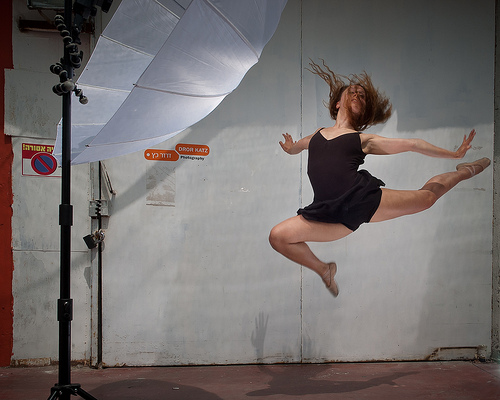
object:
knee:
[269, 221, 307, 258]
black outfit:
[297, 127, 386, 232]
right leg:
[266, 213, 321, 273]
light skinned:
[266, 58, 487, 297]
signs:
[174, 142, 211, 161]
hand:
[454, 129, 477, 159]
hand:
[279, 132, 293, 154]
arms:
[368, 138, 454, 158]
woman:
[269, 56, 490, 297]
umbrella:
[57, 0, 291, 169]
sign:
[20, 136, 64, 177]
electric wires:
[48, 11, 89, 99]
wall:
[0, 1, 494, 365]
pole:
[58, 11, 74, 386]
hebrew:
[178, 147, 208, 153]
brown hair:
[304, 57, 391, 131]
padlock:
[82, 232, 105, 249]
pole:
[96, 197, 103, 361]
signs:
[142, 148, 180, 163]